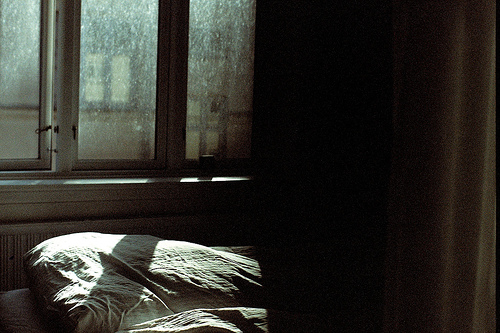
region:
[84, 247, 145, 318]
A pillow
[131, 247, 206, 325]
A pillow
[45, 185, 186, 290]
A pillow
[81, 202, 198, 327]
A pillow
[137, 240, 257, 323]
A pillow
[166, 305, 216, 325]
A pillow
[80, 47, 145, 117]
Window of a building across the street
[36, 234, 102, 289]
Light falling on a pillow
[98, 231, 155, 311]
Black shadows on a pillow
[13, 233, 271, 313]
Pillow on a bed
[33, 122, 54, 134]
Latch on a window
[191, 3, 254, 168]
Glass on a window behind a bed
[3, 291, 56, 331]
White sheet on a bed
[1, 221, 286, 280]
White striped slats on a wall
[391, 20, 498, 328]
Dark wall in a bedroom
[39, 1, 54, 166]
White wooden window pane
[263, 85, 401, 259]
the other side is dark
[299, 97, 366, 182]
the other side is dark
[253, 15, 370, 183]
the other side is dark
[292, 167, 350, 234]
the other side is dark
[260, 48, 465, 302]
the other side is dark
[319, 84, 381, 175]
the other side is dark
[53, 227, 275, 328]
a white cloth on bed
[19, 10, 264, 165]
a set of three glass doors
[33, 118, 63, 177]
small portion on the window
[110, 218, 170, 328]
a dark shadow on cloth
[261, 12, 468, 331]
the complete darkness on bed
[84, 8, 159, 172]
a small piece of glass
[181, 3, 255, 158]
a small glass with water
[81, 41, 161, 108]
shadow of the two glass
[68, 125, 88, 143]
small dust on the wood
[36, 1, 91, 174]
piece of wood to connect glass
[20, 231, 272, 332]
A pillow lying on a bed.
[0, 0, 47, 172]
Glass pane on the left of the other panes.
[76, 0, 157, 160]
Glass window pane in the middle of two other panes.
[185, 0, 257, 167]
A glass window pane to the right of two other panes.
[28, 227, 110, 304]
Sunlight reflecting on a pillow.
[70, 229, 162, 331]
Dark shadow coming across a pillow.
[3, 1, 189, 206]
White window trim all around the windows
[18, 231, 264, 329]
A white pillow with sun shining on it.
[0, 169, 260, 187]
White window sill under the panes of glass.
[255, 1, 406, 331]
Black shadow to the right of a bed.